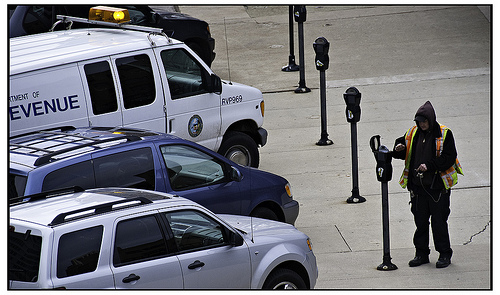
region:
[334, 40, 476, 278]
worker checking a meter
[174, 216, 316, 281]
a silver suv is parked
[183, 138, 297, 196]
this is a blue van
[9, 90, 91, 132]
the text is blue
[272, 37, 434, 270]
there are five meters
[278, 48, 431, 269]
parking meters are black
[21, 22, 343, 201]
a white government van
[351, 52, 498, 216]
man wearing a safety vest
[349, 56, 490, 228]
the man has a hoodie on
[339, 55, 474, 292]
the man has black shoes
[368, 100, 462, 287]
man checking parking meter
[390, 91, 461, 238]
man in orange and yellow vest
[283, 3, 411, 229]
five parking meters on sidewalk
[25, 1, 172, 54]
orange light on van turned on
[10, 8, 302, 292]
five vehicles parked on street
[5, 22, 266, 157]
white van with blue lettering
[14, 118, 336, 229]
blue vehicle parked near parking meter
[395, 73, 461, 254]
man wearing ball cap and hoodie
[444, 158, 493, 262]
crack on sidewalk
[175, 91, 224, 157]
circular emblem on white van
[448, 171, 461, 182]
man is wearing vest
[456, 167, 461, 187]
man is wearing vest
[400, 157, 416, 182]
man is wearing vest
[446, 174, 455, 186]
man is wearing vest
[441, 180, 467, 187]
man is wearing vest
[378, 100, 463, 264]
man standing by meter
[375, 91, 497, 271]
man wearing large brown hoodie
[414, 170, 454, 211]
man with chain in pocket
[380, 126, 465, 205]
vest of man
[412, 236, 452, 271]
black shoes of man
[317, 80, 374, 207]
parking meter by man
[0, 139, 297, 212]
blue van by man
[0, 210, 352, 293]
silver truck by man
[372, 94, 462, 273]
man wearing cap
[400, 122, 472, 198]
vest is orange and green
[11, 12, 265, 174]
city van parked by curb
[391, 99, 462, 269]
city worker checking parking meter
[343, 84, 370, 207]
black curbside parking meter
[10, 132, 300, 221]
blue minivan parked in parking space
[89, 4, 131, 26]
yellow rooftop warning light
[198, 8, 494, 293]
tan concrete sidewalk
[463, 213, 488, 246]
large crack in concrete sidewalk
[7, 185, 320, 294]
silver suv parked by curb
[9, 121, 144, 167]
black luggage rack on van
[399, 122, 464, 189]
yellow and orange construction vest